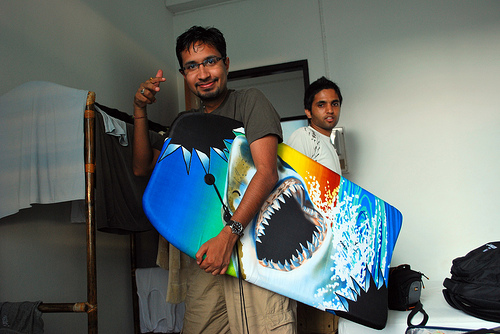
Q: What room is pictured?
A: It is a bedroom.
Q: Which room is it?
A: It is a bedroom.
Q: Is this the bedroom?
A: Yes, it is the bedroom.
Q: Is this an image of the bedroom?
A: Yes, it is showing the bedroom.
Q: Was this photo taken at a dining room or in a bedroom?
A: It was taken at a bedroom.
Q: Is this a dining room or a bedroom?
A: It is a bedroom.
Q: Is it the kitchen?
A: No, it is the bedroom.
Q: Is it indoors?
A: Yes, it is indoors.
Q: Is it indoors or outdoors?
A: It is indoors.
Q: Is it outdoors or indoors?
A: It is indoors.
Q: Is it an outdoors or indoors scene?
A: It is indoors.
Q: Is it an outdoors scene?
A: No, it is indoors.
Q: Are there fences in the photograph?
A: No, there are no fences.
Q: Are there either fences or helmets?
A: No, there are no fences or helmets.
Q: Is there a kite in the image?
A: No, there are no kites.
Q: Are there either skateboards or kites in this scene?
A: No, there are no kites or skateboards.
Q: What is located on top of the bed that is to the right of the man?
A: The luggage is on top of the bed.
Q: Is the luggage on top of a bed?
A: Yes, the luggage is on top of a bed.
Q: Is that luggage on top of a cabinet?
A: No, the luggage is on top of a bed.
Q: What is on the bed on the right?
A: The luggage is on the bed.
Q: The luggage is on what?
A: The luggage is on the bed.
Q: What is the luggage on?
A: The luggage is on the bed.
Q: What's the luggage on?
A: The luggage is on the bed.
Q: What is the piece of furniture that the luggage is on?
A: The piece of furniture is a bed.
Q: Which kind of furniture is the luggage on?
A: The luggage is on the bed.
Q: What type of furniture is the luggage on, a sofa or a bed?
A: The luggage is on a bed.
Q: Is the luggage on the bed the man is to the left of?
A: Yes, the luggage is on the bed.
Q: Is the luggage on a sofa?
A: No, the luggage is on the bed.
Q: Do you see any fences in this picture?
A: No, there are no fences.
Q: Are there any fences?
A: No, there are no fences.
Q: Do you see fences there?
A: No, there are no fences.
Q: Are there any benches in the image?
A: No, there are no benches.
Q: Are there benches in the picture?
A: No, there are no benches.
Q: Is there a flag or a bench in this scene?
A: No, there are no benches or flags.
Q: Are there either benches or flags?
A: No, there are no benches or flags.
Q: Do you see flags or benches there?
A: No, there are no benches or flags.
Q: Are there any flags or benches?
A: No, there are no benches or flags.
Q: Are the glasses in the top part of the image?
A: Yes, the glasses are in the top of the image.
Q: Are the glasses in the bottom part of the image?
A: No, the glasses are in the top of the image.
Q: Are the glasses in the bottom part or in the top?
A: The glasses are in the top of the image.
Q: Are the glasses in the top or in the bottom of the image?
A: The glasses are in the top of the image.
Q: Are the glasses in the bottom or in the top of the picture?
A: The glasses are in the top of the image.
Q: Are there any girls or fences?
A: No, there are no girls or fences.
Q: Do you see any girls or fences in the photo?
A: No, there are no girls or fences.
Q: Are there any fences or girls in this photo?
A: No, there are no girls or fences.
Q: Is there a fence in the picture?
A: No, there are no fences.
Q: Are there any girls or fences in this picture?
A: No, there are no fences or girls.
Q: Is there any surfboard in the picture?
A: Yes, there is a surfboard.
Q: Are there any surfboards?
A: Yes, there is a surfboard.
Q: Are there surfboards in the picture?
A: Yes, there is a surfboard.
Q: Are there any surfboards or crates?
A: Yes, there is a surfboard.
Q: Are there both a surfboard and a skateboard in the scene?
A: No, there is a surfboard but no skateboards.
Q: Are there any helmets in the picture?
A: No, there are no helmets.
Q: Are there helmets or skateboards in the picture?
A: No, there are no helmets or skateboards.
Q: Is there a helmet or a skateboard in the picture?
A: No, there are no helmets or skateboards.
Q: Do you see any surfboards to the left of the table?
A: Yes, there is a surfboard to the left of the table.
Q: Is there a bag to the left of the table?
A: No, there is a surfboard to the left of the table.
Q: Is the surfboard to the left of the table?
A: Yes, the surfboard is to the left of the table.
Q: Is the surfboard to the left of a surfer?
A: No, the surfboard is to the left of the table.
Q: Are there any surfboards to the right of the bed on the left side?
A: Yes, there is a surfboard to the right of the bed.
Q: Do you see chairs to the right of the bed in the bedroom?
A: No, there is a surfboard to the right of the bed.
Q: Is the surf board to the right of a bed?
A: Yes, the surf board is to the right of a bed.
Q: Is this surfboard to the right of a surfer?
A: No, the surfboard is to the right of a bed.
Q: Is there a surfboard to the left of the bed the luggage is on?
A: Yes, there is a surfboard to the left of the bed.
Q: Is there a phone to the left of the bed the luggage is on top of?
A: No, there is a surfboard to the left of the bed.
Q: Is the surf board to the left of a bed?
A: Yes, the surf board is to the left of a bed.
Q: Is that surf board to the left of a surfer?
A: No, the surf board is to the left of a bed.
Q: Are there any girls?
A: No, there are no girls.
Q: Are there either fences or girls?
A: No, there are no girls or fences.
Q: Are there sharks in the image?
A: Yes, there is a shark.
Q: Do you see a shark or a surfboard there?
A: Yes, there is a shark.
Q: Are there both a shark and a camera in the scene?
A: No, there is a shark but no cameras.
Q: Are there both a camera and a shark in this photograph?
A: No, there is a shark but no cameras.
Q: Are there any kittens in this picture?
A: No, there are no kittens.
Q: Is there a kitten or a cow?
A: No, there are no kittens or cows.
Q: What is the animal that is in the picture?
A: The animal is a shark.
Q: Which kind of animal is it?
A: The animal is a shark.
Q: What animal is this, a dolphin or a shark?
A: That is a shark.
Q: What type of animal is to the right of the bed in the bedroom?
A: The animal is a shark.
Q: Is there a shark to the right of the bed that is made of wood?
A: Yes, there is a shark to the right of the bed.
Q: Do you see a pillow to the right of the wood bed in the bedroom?
A: No, there is a shark to the right of the bed.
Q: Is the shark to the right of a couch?
A: No, the shark is to the right of the bed.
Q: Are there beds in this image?
A: Yes, there is a bed.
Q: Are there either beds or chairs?
A: Yes, there is a bed.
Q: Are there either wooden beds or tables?
A: Yes, there is a wood bed.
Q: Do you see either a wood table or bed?
A: Yes, there is a wood bed.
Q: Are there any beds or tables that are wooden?
A: Yes, the bed is wooden.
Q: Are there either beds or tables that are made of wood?
A: Yes, the bed is made of wood.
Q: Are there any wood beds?
A: Yes, there is a wood bed.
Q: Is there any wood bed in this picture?
A: Yes, there is a wood bed.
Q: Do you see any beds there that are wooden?
A: Yes, there is a bed that is wooden.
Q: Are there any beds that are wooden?
A: Yes, there is a bed that is wooden.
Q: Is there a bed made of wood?
A: Yes, there is a bed that is made of wood.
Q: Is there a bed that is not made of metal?
A: Yes, there is a bed that is made of wood.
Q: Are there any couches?
A: No, there are no couches.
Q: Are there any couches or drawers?
A: No, there are no couches or drawers.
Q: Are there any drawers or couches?
A: No, there are no couches or drawers.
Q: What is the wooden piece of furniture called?
A: The piece of furniture is a bed.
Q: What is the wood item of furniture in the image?
A: The piece of furniture is a bed.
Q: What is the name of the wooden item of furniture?
A: The piece of furniture is a bed.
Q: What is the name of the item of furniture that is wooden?
A: The piece of furniture is a bed.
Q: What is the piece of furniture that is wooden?
A: The piece of furniture is a bed.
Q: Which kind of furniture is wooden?
A: The furniture is a bed.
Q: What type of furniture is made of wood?
A: The furniture is a bed.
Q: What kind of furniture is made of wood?
A: The furniture is a bed.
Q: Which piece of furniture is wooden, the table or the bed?
A: The bed is wooden.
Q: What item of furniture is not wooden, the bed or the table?
A: The table is not wooden.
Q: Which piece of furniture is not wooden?
A: The piece of furniture is a table.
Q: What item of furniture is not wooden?
A: The piece of furniture is a table.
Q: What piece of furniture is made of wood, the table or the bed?
A: The bed is made of wood.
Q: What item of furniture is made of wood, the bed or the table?
A: The bed is made of wood.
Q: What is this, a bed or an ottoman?
A: This is a bed.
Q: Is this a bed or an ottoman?
A: This is a bed.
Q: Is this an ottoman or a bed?
A: This is a bed.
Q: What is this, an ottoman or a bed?
A: This is a bed.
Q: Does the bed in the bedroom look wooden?
A: Yes, the bed is wooden.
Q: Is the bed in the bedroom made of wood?
A: Yes, the bed is made of wood.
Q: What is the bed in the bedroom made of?
A: The bed is made of wood.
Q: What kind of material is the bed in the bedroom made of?
A: The bed is made of wood.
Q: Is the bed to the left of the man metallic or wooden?
A: The bed is wooden.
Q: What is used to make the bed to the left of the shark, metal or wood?
A: The bed is made of wood.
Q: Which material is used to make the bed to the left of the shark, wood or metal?
A: The bed is made of wood.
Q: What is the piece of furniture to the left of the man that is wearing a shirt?
A: The piece of furniture is a bed.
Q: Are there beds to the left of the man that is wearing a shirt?
A: Yes, there is a bed to the left of the man.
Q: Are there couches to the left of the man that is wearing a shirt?
A: No, there is a bed to the left of the man.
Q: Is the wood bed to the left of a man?
A: Yes, the bed is to the left of a man.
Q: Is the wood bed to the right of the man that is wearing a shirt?
A: No, the bed is to the left of the man.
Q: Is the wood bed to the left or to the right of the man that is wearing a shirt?
A: The bed is to the left of the man.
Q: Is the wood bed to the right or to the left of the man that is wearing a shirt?
A: The bed is to the left of the man.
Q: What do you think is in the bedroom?
A: The bed is in the bedroom.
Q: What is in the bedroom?
A: The bed is in the bedroom.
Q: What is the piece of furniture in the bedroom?
A: The piece of furniture is a bed.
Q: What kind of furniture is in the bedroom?
A: The piece of furniture is a bed.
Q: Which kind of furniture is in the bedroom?
A: The piece of furniture is a bed.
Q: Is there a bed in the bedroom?
A: Yes, there is a bed in the bedroom.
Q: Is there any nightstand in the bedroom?
A: No, there is a bed in the bedroom.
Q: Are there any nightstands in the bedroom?
A: No, there is a bed in the bedroom.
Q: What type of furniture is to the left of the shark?
A: The piece of furniture is a bed.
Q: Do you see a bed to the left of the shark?
A: Yes, there is a bed to the left of the shark.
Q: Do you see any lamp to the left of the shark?
A: No, there is a bed to the left of the shark.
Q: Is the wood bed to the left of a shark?
A: Yes, the bed is to the left of a shark.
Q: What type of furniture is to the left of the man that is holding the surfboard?
A: The piece of furniture is a bed.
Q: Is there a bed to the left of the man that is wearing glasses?
A: Yes, there is a bed to the left of the man.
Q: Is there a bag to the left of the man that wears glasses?
A: No, there is a bed to the left of the man.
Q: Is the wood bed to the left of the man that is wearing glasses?
A: Yes, the bed is to the left of the man.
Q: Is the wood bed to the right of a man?
A: No, the bed is to the left of a man.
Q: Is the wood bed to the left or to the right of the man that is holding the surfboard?
A: The bed is to the left of the man.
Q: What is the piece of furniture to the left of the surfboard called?
A: The piece of furniture is a bed.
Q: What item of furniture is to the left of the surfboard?
A: The piece of furniture is a bed.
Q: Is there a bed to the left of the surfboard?
A: Yes, there is a bed to the left of the surfboard.